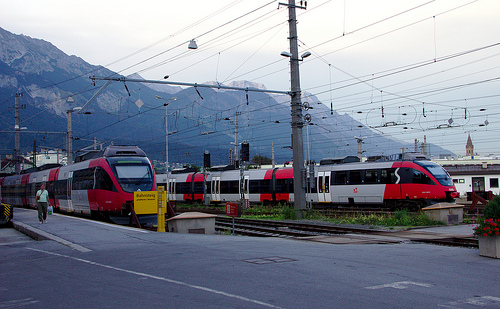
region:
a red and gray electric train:
[150, 156, 467, 223]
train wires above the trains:
[2, 1, 492, 168]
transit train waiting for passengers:
[1, 161, 170, 218]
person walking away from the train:
[26, 181, 53, 226]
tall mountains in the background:
[5, 20, 447, 157]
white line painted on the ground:
[19, 239, 279, 304]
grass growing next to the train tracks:
[237, 200, 433, 232]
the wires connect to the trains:
[3, 3, 495, 167]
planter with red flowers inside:
[473, 212, 498, 257]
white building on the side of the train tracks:
[432, 151, 498, 193]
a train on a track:
[1, 143, 158, 220]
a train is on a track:
[157, 157, 459, 211]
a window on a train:
[114, 161, 151, 181]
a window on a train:
[426, 163, 451, 180]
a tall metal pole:
[277, 0, 316, 220]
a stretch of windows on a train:
[173, 178, 293, 193]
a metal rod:
[88, 74, 290, 97]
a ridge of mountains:
[1, 25, 457, 158]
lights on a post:
[281, 48, 311, 65]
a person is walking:
[32, 183, 55, 221]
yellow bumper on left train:
[137, 188, 162, 218]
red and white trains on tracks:
[0, 144, 459, 222]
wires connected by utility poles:
[0, 0, 499, 244]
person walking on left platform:
[30, 180, 56, 223]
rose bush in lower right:
[473, 196, 499, 261]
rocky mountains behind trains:
[0, 27, 473, 161]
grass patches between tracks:
[162, 181, 434, 235]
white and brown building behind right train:
[436, 157, 498, 196]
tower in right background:
[464, 130, 476, 158]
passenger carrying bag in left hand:
[33, 178, 55, 223]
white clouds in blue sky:
[115, 5, 165, 65]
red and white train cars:
[227, 145, 417, 195]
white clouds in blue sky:
[223, 19, 253, 55]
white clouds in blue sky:
[355, 32, 377, 48]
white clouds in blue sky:
[394, 3, 432, 39]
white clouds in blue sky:
[355, 27, 407, 61]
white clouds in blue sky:
[385, 73, 426, 92]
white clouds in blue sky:
[377, 22, 448, 83]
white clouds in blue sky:
[80, 8, 132, 38]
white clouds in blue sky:
[331, 48, 367, 70]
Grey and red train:
[3, 143, 163, 220]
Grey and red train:
[156, 152, 458, 209]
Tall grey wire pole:
[274, 1, 315, 218]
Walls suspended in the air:
[0, 12, 499, 157]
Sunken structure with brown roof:
[164, 207, 224, 235]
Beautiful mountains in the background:
[3, 23, 454, 160]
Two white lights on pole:
[273, 48, 317, 69]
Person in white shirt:
[31, 181, 58, 219]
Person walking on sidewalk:
[35, 183, 55, 223]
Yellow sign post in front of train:
[130, 186, 170, 228]